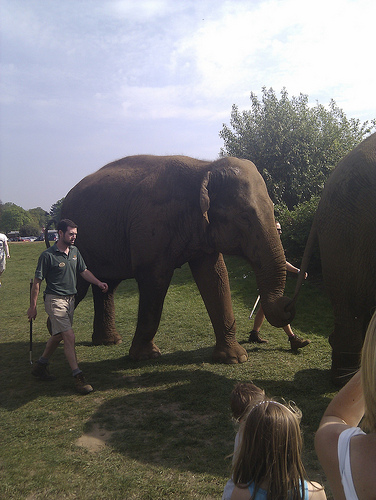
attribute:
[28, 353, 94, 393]
shoes — brown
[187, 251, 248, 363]
elephant leg — thick, large, brown, wrinkled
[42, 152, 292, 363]
elephant — wrinkled, brown, long, thick, large, four-legged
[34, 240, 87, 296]
shirt — green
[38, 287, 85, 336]
shorts — khaki